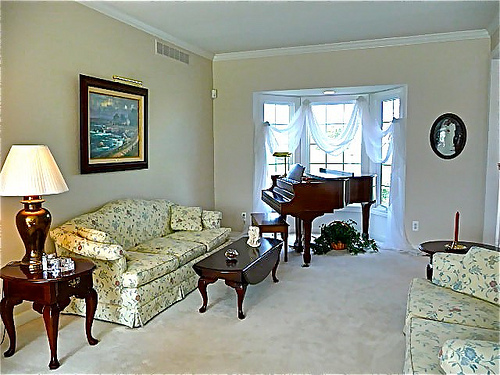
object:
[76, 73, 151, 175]
picture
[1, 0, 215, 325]
wall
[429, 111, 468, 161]
picture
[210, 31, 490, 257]
wall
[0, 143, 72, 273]
lamp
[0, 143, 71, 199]
white shade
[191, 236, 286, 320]
table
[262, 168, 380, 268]
piano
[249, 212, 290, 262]
bench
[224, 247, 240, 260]
candle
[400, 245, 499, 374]
couch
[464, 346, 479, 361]
floral print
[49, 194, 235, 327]
couch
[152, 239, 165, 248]
floral print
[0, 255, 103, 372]
end table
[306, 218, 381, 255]
plant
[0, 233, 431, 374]
floor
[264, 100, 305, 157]
curtains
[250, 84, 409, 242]
window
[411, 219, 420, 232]
electric plug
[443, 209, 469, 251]
candle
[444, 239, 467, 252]
candle holder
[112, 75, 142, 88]
light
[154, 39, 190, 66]
vent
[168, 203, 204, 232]
pillow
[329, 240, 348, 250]
basket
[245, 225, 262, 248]
decoration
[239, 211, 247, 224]
outlet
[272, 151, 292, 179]
lamp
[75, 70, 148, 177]
frame